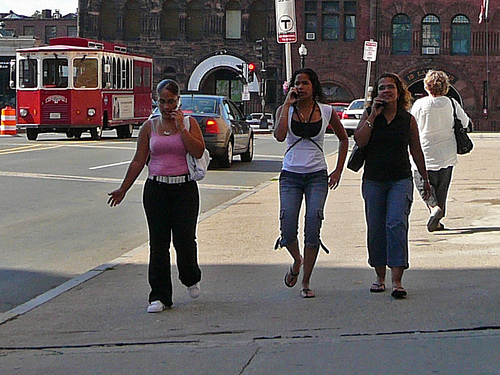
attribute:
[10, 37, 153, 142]
truck — red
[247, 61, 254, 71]
streetlight — red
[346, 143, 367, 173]
purse — black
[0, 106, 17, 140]
cone — orange, white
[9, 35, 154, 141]
trolley — red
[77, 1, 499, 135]
building — red brick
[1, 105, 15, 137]
barrel — white, orange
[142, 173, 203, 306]
pants — black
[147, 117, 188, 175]
shirt — pink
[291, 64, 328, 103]
hair — dark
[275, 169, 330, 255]
jeans — blue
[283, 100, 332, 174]
shirt — white